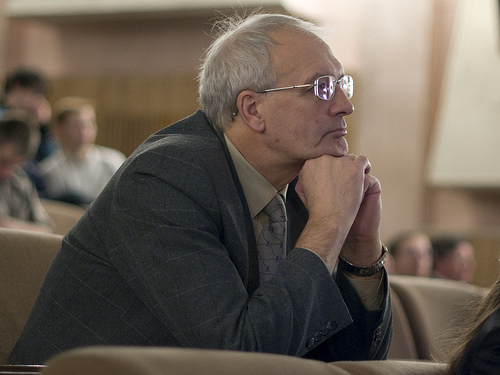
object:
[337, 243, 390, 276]
watch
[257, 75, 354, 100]
glasses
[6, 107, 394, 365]
suitcoat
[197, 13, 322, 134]
hair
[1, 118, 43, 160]
hair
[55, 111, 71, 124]
hair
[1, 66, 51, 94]
hair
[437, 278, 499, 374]
hair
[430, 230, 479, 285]
man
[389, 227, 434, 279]
man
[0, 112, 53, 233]
man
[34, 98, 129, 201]
man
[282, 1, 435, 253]
wall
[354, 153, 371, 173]
fingers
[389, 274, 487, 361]
seat cushion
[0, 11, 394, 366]
man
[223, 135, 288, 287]
dress shirt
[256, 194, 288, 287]
tie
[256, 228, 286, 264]
design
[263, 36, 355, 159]
face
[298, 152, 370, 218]
hands